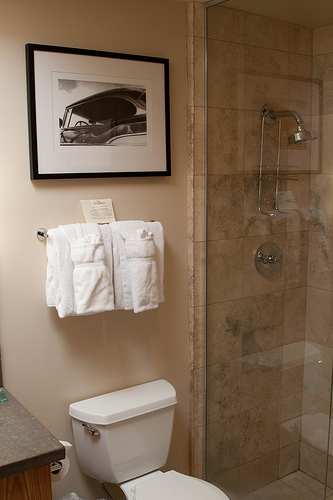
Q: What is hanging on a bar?
A: White towels.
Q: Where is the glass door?
A: Next to the toilet.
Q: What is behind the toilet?
A: Wall.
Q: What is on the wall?
A: A picture.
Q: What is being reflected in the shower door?
A: Toilet.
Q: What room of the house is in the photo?
A: Bathroom.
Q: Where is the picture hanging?
A: On the wall.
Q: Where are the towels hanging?
A: On a towel rack.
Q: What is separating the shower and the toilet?
A: A glass window.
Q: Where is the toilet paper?
A: Attached to the vanity.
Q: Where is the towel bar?
A: Above the toilet.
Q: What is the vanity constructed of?
A: Wood.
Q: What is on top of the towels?
A: A small note.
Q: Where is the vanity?
A: Beside the toilet.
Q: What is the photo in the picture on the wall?
A: A car.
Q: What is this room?
A: A bathroom.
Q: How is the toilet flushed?
A: Pushing the handle down.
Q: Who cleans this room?
A: A maid.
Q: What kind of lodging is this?
A: A rented room.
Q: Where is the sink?
A: Near the toilet.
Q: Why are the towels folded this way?
A: Make a nice presentation.